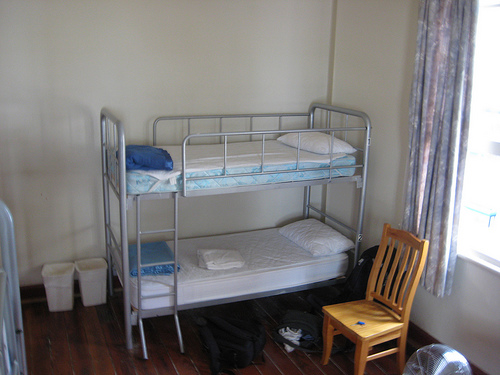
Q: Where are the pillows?
A: On the mattresses.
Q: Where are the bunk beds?
A: In the corner.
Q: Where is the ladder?
A: On the side of the bunk bed.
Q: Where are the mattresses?
A: On the bunks.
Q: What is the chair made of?
A: Wood.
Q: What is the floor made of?
A: Wood.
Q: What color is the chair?
A: Light brown.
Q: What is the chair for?
A: Sitting.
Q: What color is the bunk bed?
A: Silver.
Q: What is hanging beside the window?
A: Curtain.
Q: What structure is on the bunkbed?
A: Ladder.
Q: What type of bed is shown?
A: Bunk bed.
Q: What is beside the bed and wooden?
A: Chair.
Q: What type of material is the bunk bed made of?
A: Metal.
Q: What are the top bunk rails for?
A: Guard.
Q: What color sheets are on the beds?
A: White.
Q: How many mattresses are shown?
A: Two.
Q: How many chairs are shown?
A: 1.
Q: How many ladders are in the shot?
A: One.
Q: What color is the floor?
A: Brown.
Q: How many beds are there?
A: Two.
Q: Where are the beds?
A: In the corner.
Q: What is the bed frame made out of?
A: Metal.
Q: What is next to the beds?
A: A chair.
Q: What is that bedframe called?
A: Bunkbeds.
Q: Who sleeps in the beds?
A: People.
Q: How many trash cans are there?
A: Two.